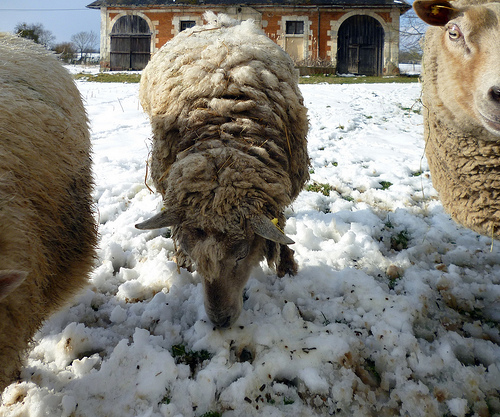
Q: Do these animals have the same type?
A: Yes, all the animals are sheep.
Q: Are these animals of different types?
A: No, all the animals are sheep.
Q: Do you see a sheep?
A: Yes, there is a sheep.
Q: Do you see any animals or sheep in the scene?
A: Yes, there is a sheep.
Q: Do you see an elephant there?
A: No, there are no elephants.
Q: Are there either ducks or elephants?
A: No, there are no elephants or ducks.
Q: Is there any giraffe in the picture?
A: No, there are no giraffes.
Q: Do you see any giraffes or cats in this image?
A: No, there are no giraffes or cats.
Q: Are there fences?
A: No, there are no fences.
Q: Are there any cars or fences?
A: No, there are no fences or cars.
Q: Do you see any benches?
A: No, there are no benches.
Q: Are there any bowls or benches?
A: No, there are no benches or bowls.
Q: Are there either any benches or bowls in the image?
A: No, there are no benches or bowls.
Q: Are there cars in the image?
A: No, there are no cars.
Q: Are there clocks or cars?
A: No, there are no cars or clocks.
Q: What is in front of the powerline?
A: The building is in front of the powerline.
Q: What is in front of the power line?
A: The building is in front of the powerline.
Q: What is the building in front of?
A: The building is in front of the wire.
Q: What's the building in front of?
A: The building is in front of the wire.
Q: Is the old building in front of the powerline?
A: Yes, the building is in front of the powerline.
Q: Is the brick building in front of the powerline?
A: Yes, the building is in front of the powerline.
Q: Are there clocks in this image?
A: No, there are no clocks.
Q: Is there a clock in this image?
A: No, there are no clocks.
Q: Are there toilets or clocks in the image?
A: No, there are no clocks or toilets.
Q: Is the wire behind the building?
A: Yes, the wire is behind the building.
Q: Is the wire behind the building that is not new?
A: Yes, the wire is behind the building.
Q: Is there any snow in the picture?
A: Yes, there is snow.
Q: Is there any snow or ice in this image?
A: Yes, there is snow.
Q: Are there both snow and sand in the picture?
A: No, there is snow but no sand.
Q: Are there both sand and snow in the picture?
A: No, there is snow but no sand.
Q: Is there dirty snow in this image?
A: Yes, there is dirty snow.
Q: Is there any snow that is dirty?
A: Yes, there is snow that is dirty.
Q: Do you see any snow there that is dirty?
A: Yes, there is snow that is dirty.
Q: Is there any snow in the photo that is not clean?
A: Yes, there is dirty snow.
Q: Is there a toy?
A: No, there are no toys.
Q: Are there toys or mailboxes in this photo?
A: No, there are no toys or mailboxes.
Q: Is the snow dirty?
A: Yes, the snow is dirty.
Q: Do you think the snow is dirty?
A: Yes, the snow is dirty.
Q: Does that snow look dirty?
A: Yes, the snow is dirty.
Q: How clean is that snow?
A: The snow is dirty.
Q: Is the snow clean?
A: No, the snow is dirty.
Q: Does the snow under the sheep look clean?
A: No, the snow is dirty.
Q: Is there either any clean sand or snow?
A: No, there is snow but it is dirty.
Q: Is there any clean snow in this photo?
A: No, there is snow but it is dirty.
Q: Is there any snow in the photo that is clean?
A: No, there is snow but it is dirty.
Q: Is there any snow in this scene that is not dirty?
A: No, there is snow but it is dirty.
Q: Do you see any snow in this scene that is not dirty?
A: No, there is snow but it is dirty.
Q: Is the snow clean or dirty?
A: The snow is dirty.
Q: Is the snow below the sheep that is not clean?
A: Yes, the snow is below the sheep.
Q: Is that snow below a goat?
A: No, the snow is below the sheep.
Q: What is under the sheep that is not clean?
A: The snow is under the sheep.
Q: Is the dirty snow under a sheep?
A: Yes, the snow is under a sheep.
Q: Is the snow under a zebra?
A: No, the snow is under a sheep.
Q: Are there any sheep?
A: Yes, there is a sheep.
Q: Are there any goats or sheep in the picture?
A: Yes, there is a sheep.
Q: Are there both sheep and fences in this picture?
A: No, there is a sheep but no fences.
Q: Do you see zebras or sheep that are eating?
A: Yes, the sheep is eating.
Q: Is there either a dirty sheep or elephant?
A: Yes, there is a dirty sheep.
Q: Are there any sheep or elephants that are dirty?
A: Yes, the sheep is dirty.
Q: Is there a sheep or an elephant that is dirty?
A: Yes, the sheep is dirty.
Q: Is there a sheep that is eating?
A: Yes, there is a sheep that is eating.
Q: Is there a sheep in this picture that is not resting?
A: Yes, there is a sheep that is eating.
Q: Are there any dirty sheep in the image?
A: Yes, there is a dirty sheep.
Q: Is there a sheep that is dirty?
A: Yes, there is a sheep that is dirty.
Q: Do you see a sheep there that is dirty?
A: Yes, there is a sheep that is dirty.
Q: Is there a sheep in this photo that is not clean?
A: Yes, there is a dirty sheep.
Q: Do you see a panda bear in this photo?
A: No, there are no panda bears.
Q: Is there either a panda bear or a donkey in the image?
A: No, there are no panda bears or donkeys.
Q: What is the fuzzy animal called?
A: The animal is a sheep.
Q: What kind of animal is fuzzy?
A: The animal is a sheep.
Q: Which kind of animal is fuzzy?
A: The animal is a sheep.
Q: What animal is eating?
A: The animal is a sheep.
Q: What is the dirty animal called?
A: The animal is a sheep.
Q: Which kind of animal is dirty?
A: The animal is a sheep.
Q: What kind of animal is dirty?
A: The animal is a sheep.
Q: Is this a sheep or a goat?
A: This is a sheep.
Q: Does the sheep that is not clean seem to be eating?
A: Yes, the sheep is eating.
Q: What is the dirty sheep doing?
A: The sheep is eating.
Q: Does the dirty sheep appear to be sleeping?
A: No, the sheep is eating.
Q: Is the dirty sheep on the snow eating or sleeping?
A: The sheep is eating.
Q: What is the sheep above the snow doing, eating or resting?
A: The sheep is eating.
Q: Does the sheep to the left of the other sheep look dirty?
A: Yes, the sheep is dirty.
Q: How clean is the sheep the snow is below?
A: The sheep is dirty.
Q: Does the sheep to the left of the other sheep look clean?
A: No, the sheep is dirty.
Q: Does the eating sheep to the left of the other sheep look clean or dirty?
A: The sheep is dirty.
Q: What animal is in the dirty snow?
A: The sheep is in the snow.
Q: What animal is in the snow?
A: The sheep is in the snow.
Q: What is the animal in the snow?
A: The animal is a sheep.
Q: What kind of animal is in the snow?
A: The animal is a sheep.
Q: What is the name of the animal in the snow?
A: The animal is a sheep.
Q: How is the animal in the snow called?
A: The animal is a sheep.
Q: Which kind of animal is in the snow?
A: The animal is a sheep.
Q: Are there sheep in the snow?
A: Yes, there is a sheep in the snow.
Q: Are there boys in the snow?
A: No, there is a sheep in the snow.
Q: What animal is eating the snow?
A: The sheep is eating the snow.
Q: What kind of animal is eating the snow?
A: The animal is a sheep.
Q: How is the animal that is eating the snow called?
A: The animal is a sheep.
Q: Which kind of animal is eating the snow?
A: The animal is a sheep.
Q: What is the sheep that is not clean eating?
A: The sheep is eating snow.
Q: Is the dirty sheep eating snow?
A: Yes, the sheep is eating snow.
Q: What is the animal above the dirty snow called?
A: The animal is a sheep.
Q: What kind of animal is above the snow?
A: The animal is a sheep.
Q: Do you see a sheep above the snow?
A: Yes, there is a sheep above the snow.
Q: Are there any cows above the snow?
A: No, there is a sheep above the snow.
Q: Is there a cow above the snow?
A: No, there is a sheep above the snow.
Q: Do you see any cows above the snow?
A: No, there is a sheep above the snow.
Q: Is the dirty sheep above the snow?
A: Yes, the sheep is above the snow.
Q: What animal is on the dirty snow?
A: The sheep is on the snow.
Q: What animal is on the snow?
A: The sheep is on the snow.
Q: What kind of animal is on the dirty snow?
A: The animal is a sheep.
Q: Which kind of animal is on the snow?
A: The animal is a sheep.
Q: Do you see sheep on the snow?
A: Yes, there is a sheep on the snow.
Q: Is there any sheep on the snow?
A: Yes, there is a sheep on the snow.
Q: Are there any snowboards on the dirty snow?
A: No, there is a sheep on the snow.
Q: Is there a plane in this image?
A: No, there are no airplanes.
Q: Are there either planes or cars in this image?
A: No, there are no planes or cars.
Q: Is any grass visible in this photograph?
A: Yes, there is grass.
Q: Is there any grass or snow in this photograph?
A: Yes, there is grass.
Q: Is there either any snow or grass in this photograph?
A: Yes, there is grass.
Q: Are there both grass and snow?
A: Yes, there are both grass and snow.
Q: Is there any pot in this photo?
A: No, there are no pots.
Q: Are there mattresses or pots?
A: No, there are no pots or mattresses.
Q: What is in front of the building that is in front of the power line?
A: The grass is in front of the building.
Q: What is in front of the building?
A: The grass is in front of the building.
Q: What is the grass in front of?
A: The grass is in front of the building.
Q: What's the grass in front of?
A: The grass is in front of the building.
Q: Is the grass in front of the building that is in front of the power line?
A: Yes, the grass is in front of the building.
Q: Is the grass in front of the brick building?
A: Yes, the grass is in front of the building.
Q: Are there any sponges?
A: No, there are no sponges.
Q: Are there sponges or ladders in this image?
A: No, there are no sponges or ladders.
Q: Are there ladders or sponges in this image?
A: No, there are no sponges or ladders.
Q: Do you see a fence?
A: No, there are no fences.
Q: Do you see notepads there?
A: No, there are no notepads.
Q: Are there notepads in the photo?
A: No, there are no notepads.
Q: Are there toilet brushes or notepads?
A: No, there are no notepads or toilet brushes.